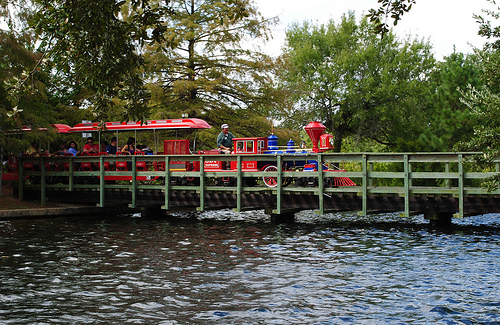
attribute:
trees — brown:
[134, 4, 252, 122]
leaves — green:
[212, 8, 277, 117]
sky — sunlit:
[254, 0, 482, 71]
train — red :
[115, 119, 355, 199]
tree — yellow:
[96, 0, 302, 146]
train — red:
[0, 115, 365, 196]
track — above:
[18, 145, 484, 208]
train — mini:
[10, 115, 361, 188]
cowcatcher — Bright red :
[304, 113, 344, 155]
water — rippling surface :
[139, 229, 464, 309]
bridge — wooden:
[229, 144, 373, 217]